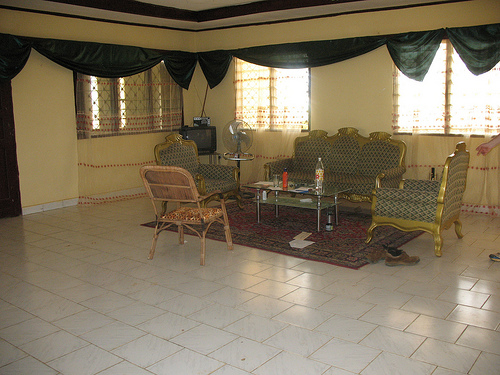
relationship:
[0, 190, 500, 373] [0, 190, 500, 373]
floor attached to floor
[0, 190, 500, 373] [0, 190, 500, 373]
floor on floor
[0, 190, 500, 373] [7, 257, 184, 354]
floor on floor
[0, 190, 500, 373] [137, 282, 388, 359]
floor on floor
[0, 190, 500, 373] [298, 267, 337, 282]
floor on floor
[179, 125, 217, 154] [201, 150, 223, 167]
television sitting on stand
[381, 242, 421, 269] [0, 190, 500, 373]
shoe on floor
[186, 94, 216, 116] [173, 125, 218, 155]
antennas on top of tv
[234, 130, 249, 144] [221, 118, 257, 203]
blades on fan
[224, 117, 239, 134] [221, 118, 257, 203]
blades on fan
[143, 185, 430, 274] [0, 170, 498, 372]
rug on floor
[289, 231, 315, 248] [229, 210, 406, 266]
white papers on rug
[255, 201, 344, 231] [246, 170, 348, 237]
legs on coffee table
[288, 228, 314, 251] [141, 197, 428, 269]
white papers on rug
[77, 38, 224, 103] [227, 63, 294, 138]
black drapes on window